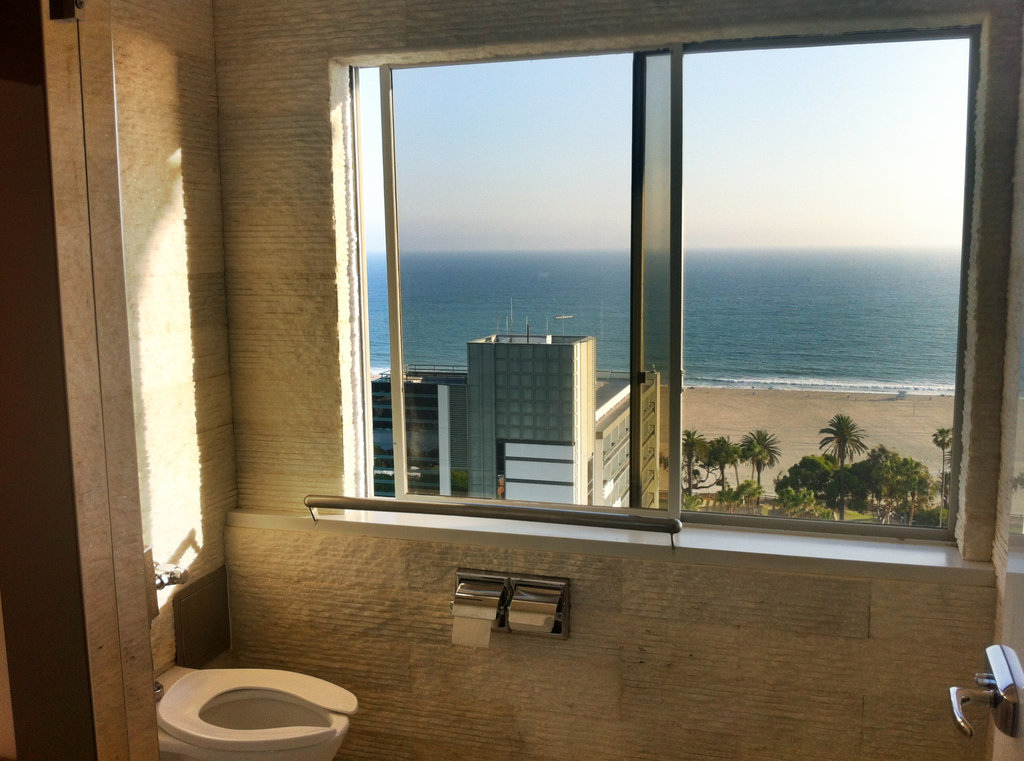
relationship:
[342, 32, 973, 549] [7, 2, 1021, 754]
window of bathroom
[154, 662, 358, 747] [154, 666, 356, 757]
seat of toilet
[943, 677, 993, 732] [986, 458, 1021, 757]
handle on door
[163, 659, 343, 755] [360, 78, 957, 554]
toilet by window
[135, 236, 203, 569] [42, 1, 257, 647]
sunlight on wall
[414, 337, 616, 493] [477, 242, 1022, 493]
building by water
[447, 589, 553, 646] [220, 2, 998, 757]
rolls on wall